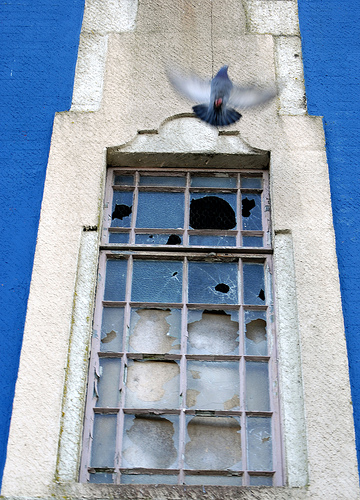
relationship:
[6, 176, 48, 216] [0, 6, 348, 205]
blue section building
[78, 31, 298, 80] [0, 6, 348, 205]
white section of building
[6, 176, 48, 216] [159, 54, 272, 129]
blue and white bird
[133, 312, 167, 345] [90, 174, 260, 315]
stone behind window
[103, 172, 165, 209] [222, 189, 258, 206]
wooden window trim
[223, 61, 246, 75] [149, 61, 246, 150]
beak of bird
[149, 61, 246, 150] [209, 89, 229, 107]
bird has feet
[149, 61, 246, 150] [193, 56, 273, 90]
bird in flight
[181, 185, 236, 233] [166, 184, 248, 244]
broken window pane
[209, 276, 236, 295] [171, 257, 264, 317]
rock hole in glass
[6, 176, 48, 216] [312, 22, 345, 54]
blue painted wall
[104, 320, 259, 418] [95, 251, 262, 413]
boad behind broken window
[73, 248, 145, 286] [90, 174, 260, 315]
white framing around window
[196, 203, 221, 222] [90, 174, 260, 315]
dark room behind window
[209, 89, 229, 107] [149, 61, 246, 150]
feet on bird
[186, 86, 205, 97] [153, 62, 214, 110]
white underside wing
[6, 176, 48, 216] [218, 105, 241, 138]
blue tail feathers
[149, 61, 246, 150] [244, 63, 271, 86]
bird in air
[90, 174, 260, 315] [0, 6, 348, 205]
window in building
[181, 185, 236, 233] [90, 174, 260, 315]
broken pane in window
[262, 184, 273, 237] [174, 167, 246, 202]
paint on frame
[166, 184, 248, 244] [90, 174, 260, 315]
pane in window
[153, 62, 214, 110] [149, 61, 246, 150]
wing on bird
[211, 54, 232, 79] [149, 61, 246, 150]
head of bird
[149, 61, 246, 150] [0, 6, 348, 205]
bird by building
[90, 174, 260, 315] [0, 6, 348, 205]
window on building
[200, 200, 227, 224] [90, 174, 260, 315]
hole in window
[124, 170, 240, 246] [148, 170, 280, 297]
panes of glass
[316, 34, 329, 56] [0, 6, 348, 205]
sky behind building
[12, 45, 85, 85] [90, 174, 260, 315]
lines on window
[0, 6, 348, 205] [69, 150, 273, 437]
building with windows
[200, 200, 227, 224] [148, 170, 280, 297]
hole in glass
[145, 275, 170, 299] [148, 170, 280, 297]
thin crack glass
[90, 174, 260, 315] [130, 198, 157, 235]
window with frosted glass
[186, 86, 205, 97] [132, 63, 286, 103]
white outstretched wings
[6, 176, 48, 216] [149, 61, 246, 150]
blue and white bird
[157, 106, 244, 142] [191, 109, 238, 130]
black and blue tail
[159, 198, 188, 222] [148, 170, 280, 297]
patch of glass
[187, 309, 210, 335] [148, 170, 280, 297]
jagged piece glass